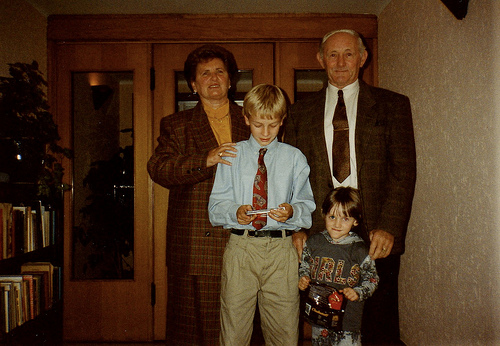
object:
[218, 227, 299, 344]
pants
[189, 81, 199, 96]
earrings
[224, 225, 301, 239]
dark belt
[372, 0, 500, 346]
wall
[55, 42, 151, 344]
door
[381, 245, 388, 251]
ring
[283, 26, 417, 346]
man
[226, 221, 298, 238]
black belt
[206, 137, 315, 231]
shirt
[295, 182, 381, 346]
child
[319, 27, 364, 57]
gray hair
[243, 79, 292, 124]
hair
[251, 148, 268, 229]
tie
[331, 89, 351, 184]
tie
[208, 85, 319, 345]
boy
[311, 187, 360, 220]
girl hair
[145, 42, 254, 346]
woman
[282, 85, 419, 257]
jacket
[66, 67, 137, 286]
glass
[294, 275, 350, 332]
toy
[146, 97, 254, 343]
jacket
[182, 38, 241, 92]
hair